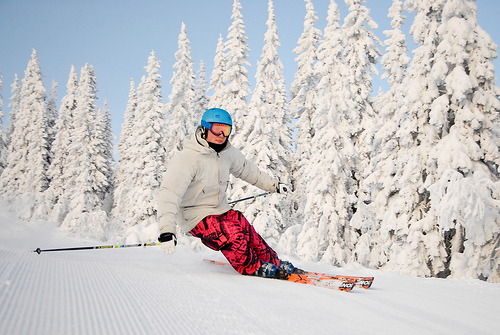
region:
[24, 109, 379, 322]
man skiing down a mountain of snow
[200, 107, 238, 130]
blue ski helmet on head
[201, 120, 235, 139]
shiny ski goggles on face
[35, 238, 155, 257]
black and white ski pole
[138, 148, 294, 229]
large white ski jacket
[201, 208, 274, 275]
red and black ski pants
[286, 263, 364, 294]
orange and white skiis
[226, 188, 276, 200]
black and white ski pole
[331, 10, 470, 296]
trees covered in snow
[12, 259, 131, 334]
grated designs on snow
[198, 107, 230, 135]
a snow ski safety helmet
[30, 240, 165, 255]
a black snow ski pole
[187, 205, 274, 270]
red and black abstract ski pants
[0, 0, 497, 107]
snow covered pine trees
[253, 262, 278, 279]
blue ski boots with silver buckles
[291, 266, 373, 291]
orange and black downhill skis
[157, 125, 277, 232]
a beige ski jacket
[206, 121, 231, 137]
blue ski goggles with amber lenses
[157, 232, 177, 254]
the skier is wearing black and white ski gloves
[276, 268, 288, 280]
the ski binders are black and orange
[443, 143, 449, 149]
part of a forest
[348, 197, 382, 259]
bottom of a tree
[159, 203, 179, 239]
part of a coat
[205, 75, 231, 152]
face of a man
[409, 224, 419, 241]
part of a branch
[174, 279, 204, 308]
part of the snow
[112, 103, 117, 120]
part of the cloud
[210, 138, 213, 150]
part of an helmet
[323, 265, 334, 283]
part of a board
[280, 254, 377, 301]
skis are orange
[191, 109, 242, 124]
blue safety helmet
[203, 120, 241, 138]
skier is wearing goggles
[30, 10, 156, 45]
sky is clear and blue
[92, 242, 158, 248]
yellow on the ski pole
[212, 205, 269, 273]
ski pants are pink and black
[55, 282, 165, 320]
snow on the ground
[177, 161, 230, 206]
skier's jacket is white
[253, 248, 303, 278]
ski boots are blue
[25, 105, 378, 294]
Skier in a steep slanting position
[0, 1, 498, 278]
Group of trees covered with thick snow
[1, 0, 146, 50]
Blue color of the open sky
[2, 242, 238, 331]
Parallel imprints on the uniform snow covered ground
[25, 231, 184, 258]
Slanted ski rod held in a hand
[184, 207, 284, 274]
Shiny red skiing trunk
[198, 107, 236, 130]
Close fitting blue helmet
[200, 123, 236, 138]
Reflective pair of skiing goggles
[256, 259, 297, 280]
Blue shaded skiing shoes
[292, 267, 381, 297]
Orange colored pair of skiis